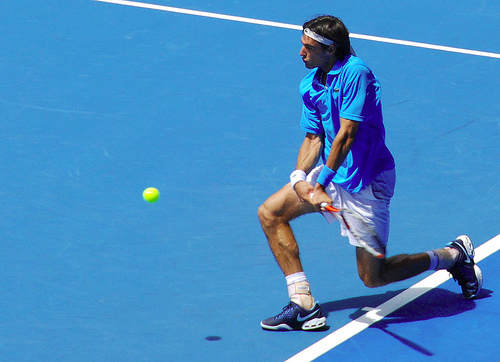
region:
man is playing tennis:
[106, 17, 490, 326]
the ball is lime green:
[101, 160, 195, 240]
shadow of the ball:
[150, 305, 235, 360]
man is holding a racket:
[217, 112, 419, 289]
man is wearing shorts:
[232, 147, 429, 304]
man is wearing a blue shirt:
[249, 45, 412, 210]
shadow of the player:
[272, 261, 489, 338]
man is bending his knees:
[180, 107, 476, 346]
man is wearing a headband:
[275, 4, 353, 61]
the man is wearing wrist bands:
[243, 151, 344, 193]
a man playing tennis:
[114, 9, 494, 339]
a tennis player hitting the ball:
[111, 5, 498, 324]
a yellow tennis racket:
[136, 182, 162, 203]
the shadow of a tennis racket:
[199, 328, 225, 344]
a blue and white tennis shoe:
[251, 290, 338, 345]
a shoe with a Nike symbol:
[255, 291, 330, 336]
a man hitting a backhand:
[230, 10, 395, 272]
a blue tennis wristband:
[311, 160, 337, 192]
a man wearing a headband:
[293, 15, 355, 81]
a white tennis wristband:
[282, 168, 310, 188]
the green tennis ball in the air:
[133, 179, 170, 209]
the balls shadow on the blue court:
[200, 323, 226, 347]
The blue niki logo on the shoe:
[294, 302, 322, 325]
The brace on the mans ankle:
[291, 284, 321, 312]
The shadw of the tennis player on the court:
[322, 286, 498, 361]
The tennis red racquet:
[316, 193, 393, 259]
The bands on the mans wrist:
[286, 159, 335, 189]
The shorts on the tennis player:
[316, 158, 403, 255]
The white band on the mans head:
[300, 18, 344, 45]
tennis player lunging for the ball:
[217, 3, 495, 340]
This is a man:
[244, 13, 495, 345]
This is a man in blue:
[254, 9, 497, 344]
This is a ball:
[136, 178, 162, 205]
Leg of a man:
[244, 169, 349, 344]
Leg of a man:
[341, 174, 488, 311]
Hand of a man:
[294, 84, 332, 218]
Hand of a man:
[309, 73, 375, 216]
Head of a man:
[294, 13, 347, 79]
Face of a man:
[299, 33, 316, 73]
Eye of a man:
[299, 36, 314, 53]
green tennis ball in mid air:
[138, 180, 159, 203]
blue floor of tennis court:
[2, 0, 493, 355]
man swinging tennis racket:
[250, 12, 487, 337]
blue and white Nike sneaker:
[257, 296, 329, 333]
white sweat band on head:
[300, 27, 335, 49]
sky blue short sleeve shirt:
[295, 54, 398, 195]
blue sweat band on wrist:
[315, 163, 335, 188]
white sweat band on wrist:
[285, 168, 307, 190]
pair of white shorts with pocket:
[302, 162, 397, 252]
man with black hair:
[295, 13, 353, 68]